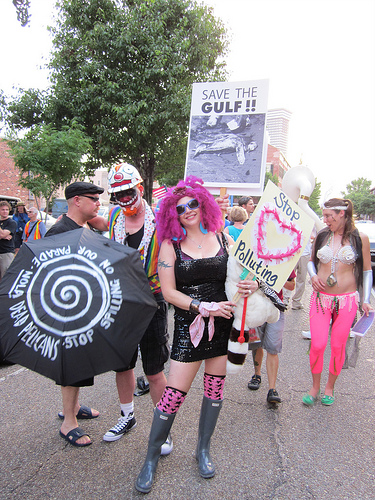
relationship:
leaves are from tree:
[0, 4, 209, 173] [10, 0, 233, 208]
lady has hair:
[132, 175, 259, 496] [156, 177, 223, 241]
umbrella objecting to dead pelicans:
[0, 225, 160, 383] [7, 301, 61, 363]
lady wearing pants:
[300, 196, 374, 412] [307, 291, 358, 375]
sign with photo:
[179, 77, 271, 197] [186, 113, 264, 184]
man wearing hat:
[98, 157, 177, 456] [107, 160, 143, 194]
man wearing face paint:
[98, 157, 177, 456] [112, 188, 143, 217]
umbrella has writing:
[0, 225, 160, 383] [10, 246, 124, 362]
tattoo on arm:
[154, 257, 172, 271] [156, 237, 238, 321]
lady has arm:
[132, 175, 259, 496] [156, 237, 238, 321]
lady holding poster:
[132, 175, 259, 496] [226, 180, 318, 303]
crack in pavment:
[264, 408, 293, 500] [0, 314, 374, 496]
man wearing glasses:
[41, 180, 105, 449] [82, 193, 103, 203]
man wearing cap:
[41, 180, 105, 449] [62, 182, 105, 200]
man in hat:
[98, 157, 177, 456] [107, 160, 143, 194]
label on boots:
[158, 413, 168, 422] [134, 398, 221, 494]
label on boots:
[210, 401, 222, 409] [134, 398, 221, 494]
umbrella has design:
[0, 225, 160, 383] [25, 252, 111, 338]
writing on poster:
[231, 237, 279, 290] [226, 180, 318, 303]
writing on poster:
[271, 188, 300, 224] [226, 180, 318, 303]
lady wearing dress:
[132, 175, 259, 496] [165, 238, 231, 361]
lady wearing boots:
[132, 175, 259, 496] [134, 398, 221, 494]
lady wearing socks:
[132, 175, 259, 496] [156, 371, 227, 418]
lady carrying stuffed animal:
[132, 175, 259, 496] [225, 238, 281, 333]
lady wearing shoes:
[300, 196, 374, 412] [302, 389, 336, 409]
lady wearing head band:
[300, 196, 374, 412] [321, 202, 350, 214]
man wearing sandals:
[41, 180, 105, 449] [55, 404, 102, 447]